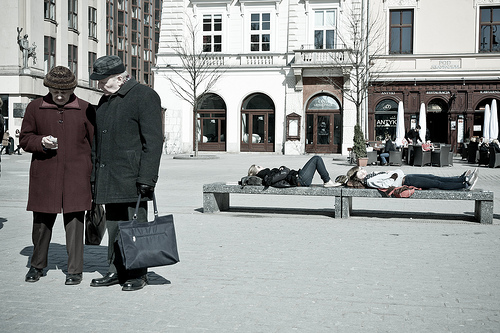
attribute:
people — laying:
[251, 142, 455, 208]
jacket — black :
[258, 167, 300, 187]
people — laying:
[239, 143, 484, 191]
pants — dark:
[402, 173, 465, 191]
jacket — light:
[362, 168, 404, 190]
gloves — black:
[136, 183, 157, 201]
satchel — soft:
[116, 187, 180, 272]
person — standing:
[87, 56, 165, 289]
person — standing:
[18, 66, 95, 283]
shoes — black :
[26, 262, 51, 282]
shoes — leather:
[93, 259, 165, 296]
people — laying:
[4, 21, 454, 269]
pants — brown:
[29, 205, 94, 282]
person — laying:
[348, 126, 473, 197]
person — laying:
[229, 125, 331, 209]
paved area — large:
[14, 157, 499, 330]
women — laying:
[230, 150, 482, 202]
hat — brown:
[41, 65, 77, 92]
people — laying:
[347, 169, 477, 189]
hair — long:
[347, 170, 369, 188]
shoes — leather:
[24, 265, 83, 285]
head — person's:
[76, 50, 145, 95]